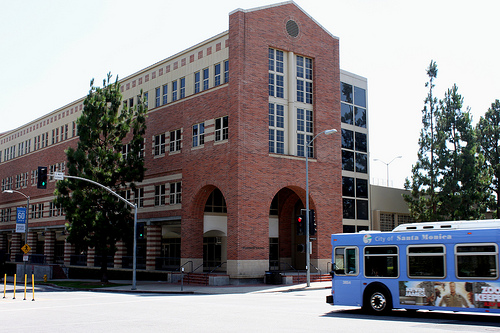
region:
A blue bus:
[306, 190, 493, 322]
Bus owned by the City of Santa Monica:
[354, 216, 461, 251]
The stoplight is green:
[36, 152, 51, 196]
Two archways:
[175, 179, 331, 278]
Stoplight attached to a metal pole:
[28, 167, 162, 290]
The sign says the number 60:
[12, 203, 37, 238]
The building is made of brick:
[3, 60, 335, 267]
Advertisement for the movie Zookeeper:
[383, 270, 498, 314]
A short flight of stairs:
[172, 260, 230, 282]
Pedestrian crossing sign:
[18, 240, 35, 256]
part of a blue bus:
[325, 217, 499, 313]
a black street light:
[33, 163, 52, 188]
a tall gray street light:
[297, 127, 339, 286]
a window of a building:
[339, 82, 354, 102]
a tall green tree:
[52, 68, 152, 278]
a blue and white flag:
[11, 201, 29, 233]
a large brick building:
[0, 3, 337, 293]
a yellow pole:
[26, 272, 41, 298]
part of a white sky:
[365, 26, 445, 66]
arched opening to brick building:
[249, 160, 314, 264]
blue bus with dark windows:
[344, 237, 499, 317]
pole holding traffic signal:
[120, 190, 157, 297]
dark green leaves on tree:
[68, 114, 117, 151]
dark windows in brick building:
[347, 88, 372, 140]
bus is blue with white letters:
[367, 224, 476, 294]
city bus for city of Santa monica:
[370, 228, 450, 258]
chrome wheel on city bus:
[356, 291, 400, 331]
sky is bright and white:
[386, 48, 407, 111]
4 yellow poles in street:
[1, 268, 40, 323]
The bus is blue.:
[325, 215, 499, 322]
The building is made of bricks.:
[0, 0, 371, 289]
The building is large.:
[0, 0, 374, 286]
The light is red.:
[296, 205, 315, 236]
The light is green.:
[38, 165, 48, 188]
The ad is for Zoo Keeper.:
[396, 280, 499, 310]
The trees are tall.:
[399, 58, 499, 227]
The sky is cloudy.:
[0, 0, 499, 204]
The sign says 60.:
[13, 205, 26, 232]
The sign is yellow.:
[19, 241, 31, 253]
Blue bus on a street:
[330, 219, 499, 315]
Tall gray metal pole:
[301, 126, 311, 285]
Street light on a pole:
[320, 127, 337, 134]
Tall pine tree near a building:
[65, 72, 146, 283]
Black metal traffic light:
[36, 166, 51, 190]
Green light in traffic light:
[40, 180, 46, 190]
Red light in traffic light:
[297, 217, 304, 224]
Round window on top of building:
[283, 17, 298, 37]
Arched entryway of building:
[266, 180, 318, 283]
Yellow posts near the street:
[2, 269, 42, 302]